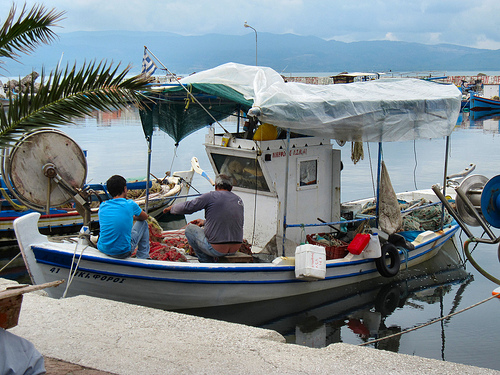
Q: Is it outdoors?
A: Yes, it is outdoors.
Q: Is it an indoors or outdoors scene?
A: It is outdoors.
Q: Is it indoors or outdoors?
A: It is outdoors.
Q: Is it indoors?
A: No, it is outdoors.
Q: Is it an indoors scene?
A: No, it is outdoors.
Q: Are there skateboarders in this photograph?
A: No, there are no skateboarders.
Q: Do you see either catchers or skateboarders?
A: No, there are no skateboarders or catchers.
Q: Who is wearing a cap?
A: The man is wearing a cap.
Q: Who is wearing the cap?
A: The man is wearing a cap.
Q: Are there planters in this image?
A: No, there are no planters.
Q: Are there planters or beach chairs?
A: No, there are no planters or beach chairs.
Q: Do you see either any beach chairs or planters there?
A: No, there are no planters or beach chairs.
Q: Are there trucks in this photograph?
A: No, there are no trucks.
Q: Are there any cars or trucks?
A: No, there are no trucks or cars.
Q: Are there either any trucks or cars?
A: No, there are no trucks or cars.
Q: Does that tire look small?
A: Yes, the tire is small.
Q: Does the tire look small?
A: Yes, the tire is small.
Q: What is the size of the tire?
A: The tire is small.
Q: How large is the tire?
A: The tire is small.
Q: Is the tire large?
A: No, the tire is small.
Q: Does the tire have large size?
A: No, the tire is small.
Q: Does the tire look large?
A: No, the tire is small.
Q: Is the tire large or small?
A: The tire is small.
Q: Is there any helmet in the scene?
A: No, there are no helmets.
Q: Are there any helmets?
A: No, there are no helmets.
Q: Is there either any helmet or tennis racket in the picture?
A: No, there are no helmets or rackets.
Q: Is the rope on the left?
A: Yes, the rope is on the left of the image.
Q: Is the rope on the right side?
A: No, the rope is on the left of the image.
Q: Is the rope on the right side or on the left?
A: The rope is on the left of the image.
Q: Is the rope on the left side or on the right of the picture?
A: The rope is on the left of the image.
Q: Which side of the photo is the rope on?
A: The rope is on the left of the image.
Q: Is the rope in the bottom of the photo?
A: Yes, the rope is in the bottom of the image.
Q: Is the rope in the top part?
A: No, the rope is in the bottom of the image.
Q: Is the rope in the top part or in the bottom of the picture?
A: The rope is in the bottom of the image.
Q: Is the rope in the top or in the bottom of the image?
A: The rope is in the bottom of the image.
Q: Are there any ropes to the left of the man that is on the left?
A: Yes, there is a rope to the left of the man.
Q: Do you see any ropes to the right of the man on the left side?
A: No, the rope is to the left of the man.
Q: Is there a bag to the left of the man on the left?
A: No, there is a rope to the left of the man.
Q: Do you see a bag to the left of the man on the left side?
A: No, there is a rope to the left of the man.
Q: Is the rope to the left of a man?
A: Yes, the rope is to the left of a man.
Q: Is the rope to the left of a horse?
A: No, the rope is to the left of a man.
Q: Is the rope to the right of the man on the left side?
A: No, the rope is to the left of the man.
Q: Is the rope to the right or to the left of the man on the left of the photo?
A: The rope is to the left of the man.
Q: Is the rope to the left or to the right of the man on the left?
A: The rope is to the left of the man.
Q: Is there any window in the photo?
A: Yes, there is a window.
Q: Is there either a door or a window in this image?
A: Yes, there is a window.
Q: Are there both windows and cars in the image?
A: No, there is a window but no cars.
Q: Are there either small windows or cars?
A: Yes, there is a small window.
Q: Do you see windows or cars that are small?
A: Yes, the window is small.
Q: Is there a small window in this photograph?
A: Yes, there is a small window.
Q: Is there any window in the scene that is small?
A: Yes, there is a window that is small.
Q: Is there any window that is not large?
A: Yes, there is a small window.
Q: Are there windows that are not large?
A: Yes, there is a small window.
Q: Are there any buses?
A: No, there are no buses.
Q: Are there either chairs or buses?
A: No, there are no buses or chairs.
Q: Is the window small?
A: Yes, the window is small.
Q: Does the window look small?
A: Yes, the window is small.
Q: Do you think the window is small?
A: Yes, the window is small.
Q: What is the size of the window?
A: The window is small.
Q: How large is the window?
A: The window is small.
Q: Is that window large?
A: No, the window is small.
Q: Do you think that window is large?
A: No, the window is small.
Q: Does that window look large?
A: No, the window is small.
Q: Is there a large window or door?
A: No, there is a window but it is small.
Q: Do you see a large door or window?
A: No, there is a window but it is small.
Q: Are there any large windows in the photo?
A: No, there is a window but it is small.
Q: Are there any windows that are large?
A: No, there is a window but it is small.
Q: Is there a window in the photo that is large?
A: No, there is a window but it is small.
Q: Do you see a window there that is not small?
A: No, there is a window but it is small.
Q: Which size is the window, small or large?
A: The window is small.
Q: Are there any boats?
A: Yes, there is a boat.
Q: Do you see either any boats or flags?
A: Yes, there is a boat.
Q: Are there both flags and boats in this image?
A: Yes, there are both a boat and a flag.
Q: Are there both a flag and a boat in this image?
A: Yes, there are both a boat and a flag.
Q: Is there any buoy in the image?
A: No, there are no buoys.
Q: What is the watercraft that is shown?
A: The watercraft is a boat.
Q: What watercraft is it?
A: The watercraft is a boat.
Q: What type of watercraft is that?
A: This is a boat.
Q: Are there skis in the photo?
A: No, there are no skis.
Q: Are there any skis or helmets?
A: No, there are no skis or helmets.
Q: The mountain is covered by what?
A: The mountain is covered by the clouds.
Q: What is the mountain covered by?
A: The mountain is covered by the clouds.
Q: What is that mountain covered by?
A: The mountain is covered by the clouds.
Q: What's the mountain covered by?
A: The mountain is covered by the clouds.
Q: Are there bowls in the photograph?
A: No, there are no bowls.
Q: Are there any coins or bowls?
A: No, there are no bowls or coins.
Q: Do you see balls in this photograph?
A: No, there are no balls.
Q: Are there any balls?
A: No, there are no balls.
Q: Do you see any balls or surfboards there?
A: No, there are no balls or surfboards.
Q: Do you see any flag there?
A: Yes, there is a flag.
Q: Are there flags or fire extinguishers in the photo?
A: Yes, there is a flag.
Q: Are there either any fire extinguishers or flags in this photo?
A: Yes, there is a flag.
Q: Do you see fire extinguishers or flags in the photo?
A: Yes, there is a flag.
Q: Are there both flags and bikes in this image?
A: No, there is a flag but no bikes.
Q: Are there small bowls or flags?
A: Yes, there is a small flag.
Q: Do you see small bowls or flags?
A: Yes, there is a small flag.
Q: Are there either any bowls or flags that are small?
A: Yes, the flag is small.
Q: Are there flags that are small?
A: Yes, there is a small flag.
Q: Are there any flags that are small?
A: Yes, there is a flag that is small.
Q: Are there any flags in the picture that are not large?
A: Yes, there is a small flag.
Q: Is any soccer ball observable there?
A: No, there are no soccer balls.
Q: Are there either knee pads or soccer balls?
A: No, there are no soccer balls or knee pads.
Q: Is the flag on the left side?
A: Yes, the flag is on the left of the image.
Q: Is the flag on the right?
A: No, the flag is on the left of the image.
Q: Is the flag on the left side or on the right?
A: The flag is on the left of the image.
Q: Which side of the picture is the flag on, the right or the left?
A: The flag is on the left of the image.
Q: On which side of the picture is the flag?
A: The flag is on the left of the image.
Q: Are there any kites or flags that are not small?
A: No, there is a flag but it is small.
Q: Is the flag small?
A: Yes, the flag is small.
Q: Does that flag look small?
A: Yes, the flag is small.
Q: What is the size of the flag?
A: The flag is small.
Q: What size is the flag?
A: The flag is small.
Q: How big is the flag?
A: The flag is small.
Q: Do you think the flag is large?
A: No, the flag is small.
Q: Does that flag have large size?
A: No, the flag is small.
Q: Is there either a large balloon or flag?
A: No, there is a flag but it is small.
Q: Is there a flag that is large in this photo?
A: No, there is a flag but it is small.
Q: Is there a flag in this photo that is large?
A: No, there is a flag but it is small.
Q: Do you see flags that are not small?
A: No, there is a flag but it is small.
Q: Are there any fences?
A: No, there are no fences.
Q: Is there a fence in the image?
A: No, there are no fences.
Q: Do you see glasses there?
A: No, there are no glasses.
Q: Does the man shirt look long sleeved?
A: Yes, the shirt is long sleeved.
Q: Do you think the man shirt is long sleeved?
A: Yes, the shirt is long sleeved.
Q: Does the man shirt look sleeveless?
A: No, the shirt is long sleeved.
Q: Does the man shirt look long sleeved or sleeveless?
A: The shirt is long sleeved.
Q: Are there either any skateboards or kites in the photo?
A: No, there are no kites or skateboards.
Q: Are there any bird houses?
A: No, there are no bird houses.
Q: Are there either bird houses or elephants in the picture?
A: No, there are no bird houses or elephants.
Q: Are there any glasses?
A: No, there are no glasses.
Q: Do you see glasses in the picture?
A: No, there are no glasses.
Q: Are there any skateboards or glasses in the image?
A: No, there are no glasses or skateboards.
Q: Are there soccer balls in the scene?
A: No, there are no soccer balls.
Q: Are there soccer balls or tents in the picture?
A: No, there are no soccer balls or tents.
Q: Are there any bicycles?
A: No, there are no bicycles.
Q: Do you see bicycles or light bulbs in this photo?
A: No, there are no bicycles or light bulbs.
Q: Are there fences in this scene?
A: No, there are no fences.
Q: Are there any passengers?
A: No, there are no passengers.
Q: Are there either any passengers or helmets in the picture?
A: No, there are no passengers or helmets.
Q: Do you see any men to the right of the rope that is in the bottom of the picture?
A: Yes, there is a man to the right of the rope.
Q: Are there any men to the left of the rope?
A: No, the man is to the right of the rope.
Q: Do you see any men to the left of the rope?
A: No, the man is to the right of the rope.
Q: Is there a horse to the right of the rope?
A: No, there is a man to the right of the rope.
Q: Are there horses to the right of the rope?
A: No, there is a man to the right of the rope.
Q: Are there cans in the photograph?
A: Yes, there is a can.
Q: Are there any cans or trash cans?
A: Yes, there is a can.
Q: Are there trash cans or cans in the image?
A: Yes, there is a can.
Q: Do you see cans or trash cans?
A: Yes, there is a can.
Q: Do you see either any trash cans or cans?
A: Yes, there is a can.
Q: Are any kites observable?
A: No, there are no kites.